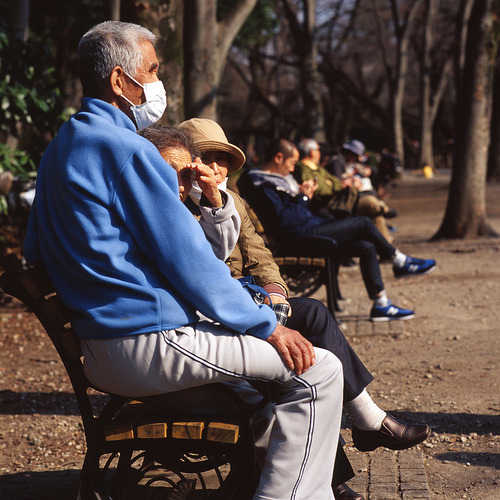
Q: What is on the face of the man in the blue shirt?
A: Air pollution mask.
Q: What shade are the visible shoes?
A: Blue.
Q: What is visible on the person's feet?
A: Blue shoes.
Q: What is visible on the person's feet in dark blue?
A: Blue shoes.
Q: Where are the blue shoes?
A: Visible in center.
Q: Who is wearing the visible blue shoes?
A: Person in dark blue on middle bench.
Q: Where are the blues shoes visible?
A: On a person's feet.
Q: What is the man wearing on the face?
A: A face mask.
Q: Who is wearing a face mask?
A: Man in blue shirt.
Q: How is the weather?
A: Sunny.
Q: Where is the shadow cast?
A: On ground.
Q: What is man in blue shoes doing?
A: Using cellphone.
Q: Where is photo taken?
A: At park.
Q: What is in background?
A: Large trees.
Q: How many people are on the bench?
A: Three.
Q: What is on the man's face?
A: Mask.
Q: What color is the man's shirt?
A: Blue.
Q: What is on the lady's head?
A: Hat.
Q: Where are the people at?
A: Park.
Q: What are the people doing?
A: Sitting.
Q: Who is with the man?
A: Two ladies.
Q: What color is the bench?
A: Brown.